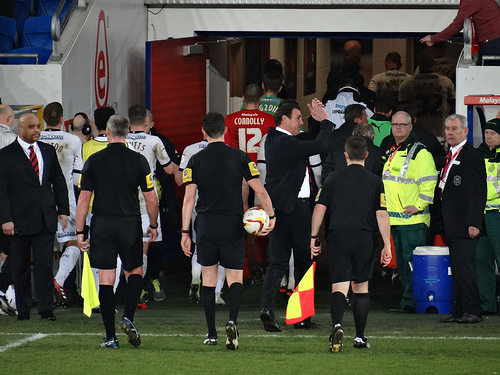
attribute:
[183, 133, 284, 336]
referee —  Three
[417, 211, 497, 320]
water cooler —   blue, for water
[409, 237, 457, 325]
cooler — blue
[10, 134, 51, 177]
tie — striped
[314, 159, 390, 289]
uniform — black and yellow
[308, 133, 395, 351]
man — young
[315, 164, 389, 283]
uniform — black and yellow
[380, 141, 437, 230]
jacket —  yellow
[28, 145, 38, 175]
tie — red, black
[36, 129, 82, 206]
shirt — white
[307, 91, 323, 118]
hand —  man's,  in air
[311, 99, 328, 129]
hand —  man's,  in air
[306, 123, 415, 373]
man —  in uniform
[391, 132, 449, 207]
jacket — yellow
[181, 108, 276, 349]
man — young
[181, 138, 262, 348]
uniform — black and yellow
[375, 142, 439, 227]
shirt —  yellow and gray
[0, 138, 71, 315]
suit —  blue 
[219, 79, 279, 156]
red jersey —   player's,  in tunnel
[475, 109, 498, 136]
toboggan hat — black, knit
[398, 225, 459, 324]
cooler —  Blue and white, for water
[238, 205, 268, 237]
ball —  red and white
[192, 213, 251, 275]
shorts — black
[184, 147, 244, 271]
soccer uniform — black and yellow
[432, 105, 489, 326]
man — standing, watching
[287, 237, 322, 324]
flag — checkered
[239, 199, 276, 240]
ball — red and white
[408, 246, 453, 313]
water jug — blue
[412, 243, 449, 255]
lid — white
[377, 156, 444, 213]
top — reflective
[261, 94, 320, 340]
man — walking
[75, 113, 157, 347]
man — young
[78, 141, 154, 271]
uniform — black, yellow, soccer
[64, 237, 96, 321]
cloth — yellow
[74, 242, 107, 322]
towel — yellow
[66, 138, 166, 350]
uniform — black and yellow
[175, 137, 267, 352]
uniform — black and yellow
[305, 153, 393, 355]
uniform — black and yellow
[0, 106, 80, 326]
man —  in black tuxedo